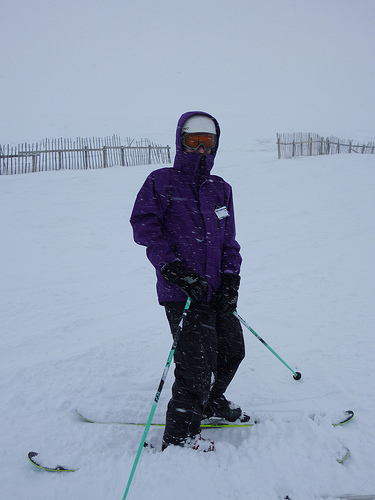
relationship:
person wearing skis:
[130, 111, 244, 453] [31, 406, 354, 468]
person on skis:
[130, 111, 244, 453] [31, 406, 354, 468]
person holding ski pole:
[130, 111, 244, 453] [96, 298, 193, 499]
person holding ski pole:
[130, 111, 244, 453] [227, 311, 301, 379]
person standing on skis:
[130, 111, 244, 453] [31, 406, 354, 468]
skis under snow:
[31, 406, 354, 468] [0, 153, 372, 499]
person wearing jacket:
[130, 111, 244, 453] [131, 114, 239, 304]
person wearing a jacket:
[130, 111, 244, 453] [131, 114, 239, 304]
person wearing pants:
[130, 111, 244, 453] [164, 304, 246, 439]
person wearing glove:
[130, 111, 244, 453] [219, 272, 240, 310]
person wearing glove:
[130, 111, 244, 453] [162, 257, 206, 302]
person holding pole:
[130, 111, 244, 453] [96, 298, 193, 499]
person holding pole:
[130, 111, 244, 453] [227, 311, 301, 379]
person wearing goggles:
[130, 111, 244, 453] [179, 132, 217, 151]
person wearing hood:
[130, 111, 244, 453] [175, 111, 219, 175]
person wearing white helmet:
[130, 111, 244, 453] [182, 115, 218, 136]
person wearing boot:
[130, 111, 244, 453] [164, 400, 215, 451]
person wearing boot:
[130, 111, 244, 453] [204, 380, 240, 420]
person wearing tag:
[130, 111, 244, 453] [214, 206, 230, 220]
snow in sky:
[0, 153, 372, 499] [1, 0, 368, 148]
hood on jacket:
[175, 111, 219, 175] [131, 114, 239, 304]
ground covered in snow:
[3, 155, 374, 499] [0, 153, 372, 499]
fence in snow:
[277, 135, 374, 156] [0, 153, 372, 499]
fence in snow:
[0, 138, 172, 176] [0, 153, 372, 499]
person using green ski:
[130, 111, 244, 453] [203, 423, 254, 428]